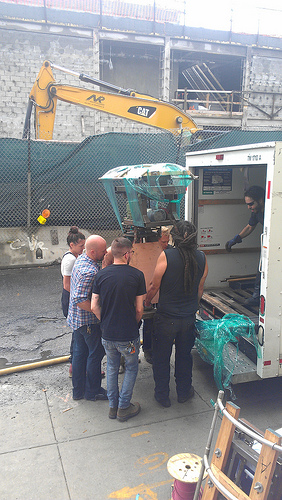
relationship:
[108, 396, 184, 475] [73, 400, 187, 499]
concrete has stains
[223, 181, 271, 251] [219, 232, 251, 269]
man wearing glove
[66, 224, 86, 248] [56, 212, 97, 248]
bun in bun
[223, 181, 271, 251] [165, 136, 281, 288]
man in back